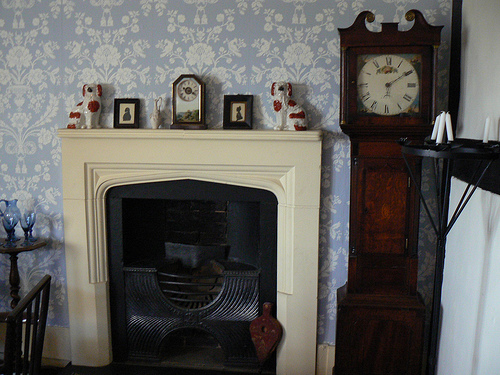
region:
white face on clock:
[321, 6, 437, 126]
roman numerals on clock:
[351, 44, 438, 125]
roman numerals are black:
[353, 44, 431, 137]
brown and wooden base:
[336, 136, 429, 374]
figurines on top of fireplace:
[61, 83, 336, 129]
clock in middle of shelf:
[146, 61, 241, 144]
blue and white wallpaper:
[41, 18, 151, 85]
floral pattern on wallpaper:
[63, 11, 166, 63]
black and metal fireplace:
[134, 214, 254, 322]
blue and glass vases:
[1, 188, 29, 250]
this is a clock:
[357, 50, 420, 117]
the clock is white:
[373, 72, 389, 99]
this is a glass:
[21, 206, 35, 231]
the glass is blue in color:
[9, 206, 23, 224]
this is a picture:
[223, 94, 257, 131]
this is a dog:
[262, 73, 312, 130]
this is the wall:
[54, 16, 211, 61]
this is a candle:
[441, 108, 462, 133]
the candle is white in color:
[438, 111, 453, 123]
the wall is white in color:
[478, 25, 498, 61]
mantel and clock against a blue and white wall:
[51, 5, 440, 366]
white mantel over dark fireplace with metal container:
[55, 120, 317, 370]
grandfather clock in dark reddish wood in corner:
[335, 5, 440, 370]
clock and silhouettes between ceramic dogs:
[63, 71, 313, 127]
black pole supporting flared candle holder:
[390, 105, 490, 367]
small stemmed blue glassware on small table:
[0, 195, 50, 306]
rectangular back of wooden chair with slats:
[0, 265, 50, 365]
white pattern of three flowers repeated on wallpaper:
[0, 5, 320, 115]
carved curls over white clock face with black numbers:
[335, 7, 440, 137]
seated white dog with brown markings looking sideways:
[267, 75, 307, 125]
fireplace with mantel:
[50, 126, 350, 372]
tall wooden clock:
[320, 10, 445, 373]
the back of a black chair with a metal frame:
[6, 273, 66, 368]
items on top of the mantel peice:
[48, 73, 319, 126]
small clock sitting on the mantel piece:
[165, 72, 212, 132]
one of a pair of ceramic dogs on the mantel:
[265, 77, 312, 132]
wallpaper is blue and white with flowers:
[7, 2, 433, 372]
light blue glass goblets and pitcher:
[3, 196, 41, 247]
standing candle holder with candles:
[390, 107, 490, 372]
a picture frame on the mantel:
[221, 93, 255, 128]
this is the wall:
[463, 35, 479, 73]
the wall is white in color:
[454, 313, 485, 355]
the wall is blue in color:
[236, 20, 255, 37]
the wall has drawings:
[170, 19, 266, 65]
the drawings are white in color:
[191, 8, 266, 55]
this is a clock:
[358, 63, 414, 118]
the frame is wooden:
[365, 151, 393, 203]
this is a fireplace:
[134, 230, 262, 322]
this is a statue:
[63, 73, 102, 125]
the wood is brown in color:
[371, 135, 388, 147]